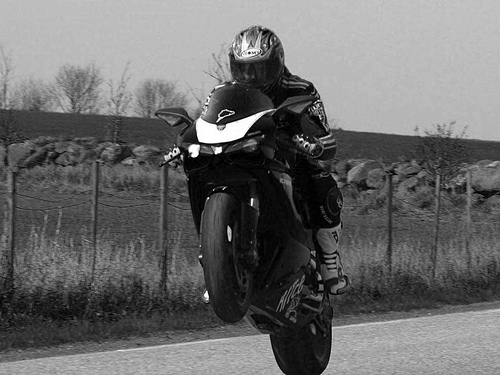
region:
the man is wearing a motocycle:
[230, 26, 286, 86]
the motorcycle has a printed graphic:
[228, 25, 284, 84]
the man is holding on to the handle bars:
[162, 125, 324, 172]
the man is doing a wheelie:
[171, 24, 342, 374]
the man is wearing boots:
[313, 221, 350, 296]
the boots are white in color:
[309, 223, 354, 295]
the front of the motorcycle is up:
[173, 116, 280, 340]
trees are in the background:
[2, 55, 197, 133]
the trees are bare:
[2, 51, 196, 131]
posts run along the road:
[2, 159, 497, 307]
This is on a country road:
[20, 3, 484, 368]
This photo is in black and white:
[18, 16, 469, 354]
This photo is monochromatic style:
[30, 19, 479, 334]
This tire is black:
[202, 203, 264, 334]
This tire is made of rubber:
[199, 211, 242, 344]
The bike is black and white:
[167, 63, 344, 183]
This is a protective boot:
[296, 162, 385, 317]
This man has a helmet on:
[227, 15, 294, 88]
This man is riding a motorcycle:
[139, 20, 389, 354]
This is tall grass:
[25, 213, 158, 336]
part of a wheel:
[220, 282, 245, 310]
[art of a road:
[396, 333, 418, 358]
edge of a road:
[223, 281, 237, 298]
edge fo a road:
[93, 297, 149, 350]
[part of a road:
[416, 316, 435, 343]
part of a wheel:
[213, 277, 238, 315]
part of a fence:
[107, 208, 144, 259]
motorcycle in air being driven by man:
[154, 78, 356, 372]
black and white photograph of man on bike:
[7, 3, 485, 368]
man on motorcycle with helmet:
[165, 13, 355, 294]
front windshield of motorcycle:
[171, 75, 288, 180]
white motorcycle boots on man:
[310, 220, 353, 300]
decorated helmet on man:
[222, 20, 286, 102]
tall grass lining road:
[4, 203, 494, 351]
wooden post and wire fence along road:
[7, 160, 499, 315]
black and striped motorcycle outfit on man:
[206, 68, 341, 232]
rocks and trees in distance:
[0, 33, 498, 216]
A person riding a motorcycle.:
[181, 14, 358, 346]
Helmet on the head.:
[221, 20, 298, 94]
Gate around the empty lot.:
[10, 168, 178, 289]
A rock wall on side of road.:
[357, 157, 488, 218]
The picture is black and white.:
[62, 41, 447, 346]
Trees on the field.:
[25, 60, 177, 130]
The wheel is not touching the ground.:
[171, 166, 271, 332]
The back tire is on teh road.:
[260, 310, 345, 370]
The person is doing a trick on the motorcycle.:
[191, 8, 358, 357]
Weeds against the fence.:
[41, 220, 178, 310]